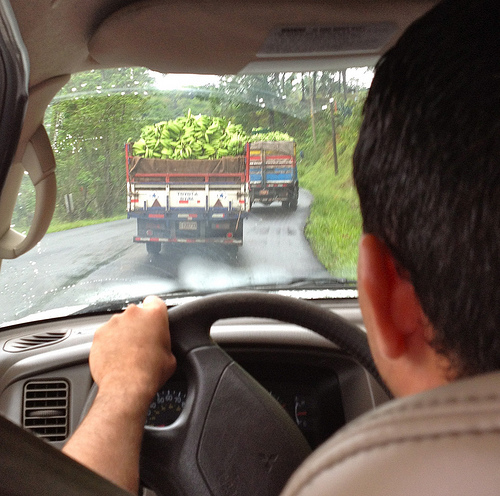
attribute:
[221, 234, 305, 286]
road — grey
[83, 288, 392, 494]
steering wheel — black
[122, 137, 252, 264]
truck — white , red 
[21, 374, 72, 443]
vent — grey 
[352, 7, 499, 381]
hair — brown 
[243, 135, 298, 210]
truck — red , blue 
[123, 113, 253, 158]
bananas — green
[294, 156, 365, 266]
grass — green 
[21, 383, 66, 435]
vents — airconditioning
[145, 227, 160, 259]
wheel — black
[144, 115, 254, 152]
bananas — unripe